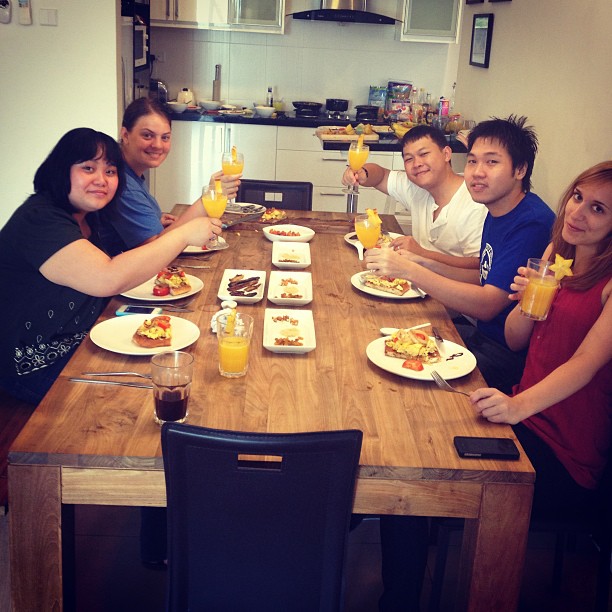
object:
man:
[341, 124, 488, 268]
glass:
[342, 141, 370, 194]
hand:
[470, 388, 519, 426]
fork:
[430, 370, 470, 397]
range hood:
[287, 0, 401, 26]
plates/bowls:
[167, 88, 286, 119]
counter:
[146, 103, 467, 215]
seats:
[235, 179, 312, 210]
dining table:
[6, 203, 539, 610]